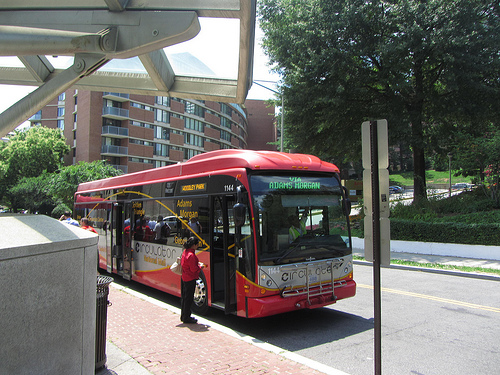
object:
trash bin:
[96, 275, 115, 375]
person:
[179, 234, 203, 324]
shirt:
[181, 248, 202, 282]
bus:
[73, 148, 358, 318]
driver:
[290, 206, 310, 242]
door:
[209, 194, 238, 312]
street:
[0, 180, 500, 374]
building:
[25, 53, 281, 172]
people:
[59, 210, 101, 269]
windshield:
[248, 191, 353, 265]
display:
[248, 172, 343, 192]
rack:
[259, 256, 353, 288]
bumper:
[247, 280, 358, 315]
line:
[356, 280, 500, 309]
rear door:
[107, 202, 132, 281]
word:
[269, 177, 320, 190]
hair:
[185, 237, 200, 249]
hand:
[301, 205, 308, 219]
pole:
[369, 119, 384, 372]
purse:
[171, 255, 183, 281]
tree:
[258, 2, 500, 207]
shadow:
[97, 266, 374, 352]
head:
[185, 236, 201, 251]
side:
[106, 283, 348, 375]